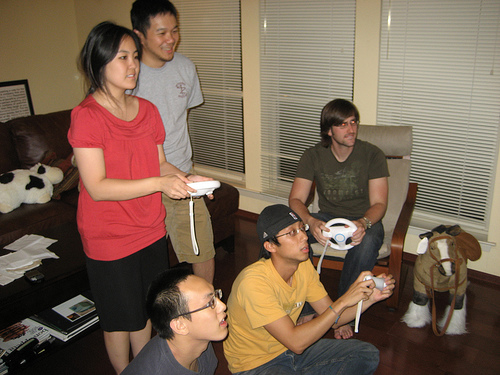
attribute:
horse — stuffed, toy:
[400, 225, 467, 335]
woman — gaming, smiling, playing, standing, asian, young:
[66, 22, 216, 374]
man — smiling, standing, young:
[130, 1, 215, 287]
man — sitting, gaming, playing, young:
[282, 99, 388, 305]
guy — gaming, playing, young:
[220, 204, 395, 375]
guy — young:
[124, 263, 231, 375]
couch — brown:
[1, 106, 239, 256]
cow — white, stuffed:
[0, 162, 64, 214]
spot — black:
[25, 172, 45, 191]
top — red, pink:
[65, 96, 167, 263]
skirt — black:
[84, 236, 171, 333]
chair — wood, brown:
[304, 123, 419, 313]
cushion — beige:
[311, 124, 413, 259]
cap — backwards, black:
[258, 202, 302, 243]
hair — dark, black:
[146, 265, 192, 339]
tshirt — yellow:
[220, 256, 329, 373]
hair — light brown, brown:
[319, 99, 359, 150]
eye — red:
[348, 118, 355, 124]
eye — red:
[338, 119, 349, 128]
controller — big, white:
[178, 179, 220, 255]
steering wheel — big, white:
[314, 216, 357, 274]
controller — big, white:
[353, 276, 389, 333]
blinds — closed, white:
[259, 0, 355, 214]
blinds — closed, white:
[171, 0, 243, 182]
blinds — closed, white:
[377, 1, 498, 243]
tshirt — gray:
[124, 49, 206, 173]